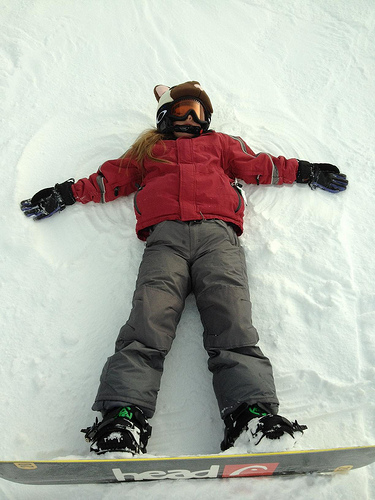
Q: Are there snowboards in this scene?
A: Yes, there is a snowboard.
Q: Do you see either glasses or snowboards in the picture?
A: Yes, there is a snowboard.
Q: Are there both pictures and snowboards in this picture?
A: No, there is a snowboard but no pictures.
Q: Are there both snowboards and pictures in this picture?
A: No, there is a snowboard but no pictures.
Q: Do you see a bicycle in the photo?
A: No, there are no bicycles.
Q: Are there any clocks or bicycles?
A: No, there are no bicycles or clocks.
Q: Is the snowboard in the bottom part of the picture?
A: Yes, the snowboard is in the bottom of the image.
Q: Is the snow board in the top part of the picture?
A: No, the snow board is in the bottom of the image.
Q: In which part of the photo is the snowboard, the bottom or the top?
A: The snowboard is in the bottom of the image.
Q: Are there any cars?
A: No, there are no cars.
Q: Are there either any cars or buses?
A: No, there are no cars or buses.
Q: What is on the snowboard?
A: The word is on the snowboard.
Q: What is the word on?
A: The word is on the snowboard.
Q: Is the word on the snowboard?
A: Yes, the word is on the snowboard.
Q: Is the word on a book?
A: No, the word is on the snowboard.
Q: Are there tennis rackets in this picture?
A: No, there are no tennis rackets.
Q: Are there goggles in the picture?
A: Yes, there are goggles.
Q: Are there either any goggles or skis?
A: Yes, there are goggles.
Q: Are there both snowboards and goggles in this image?
A: Yes, there are both goggles and a snowboard.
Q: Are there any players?
A: No, there are no players.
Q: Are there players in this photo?
A: No, there are no players.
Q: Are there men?
A: No, there are no men.